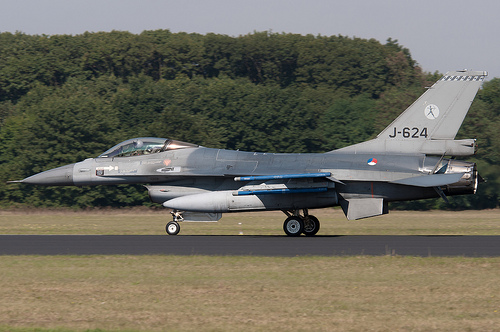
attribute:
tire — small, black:
[283, 213, 306, 238]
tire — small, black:
[304, 213, 322, 236]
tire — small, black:
[165, 217, 181, 238]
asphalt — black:
[0, 233, 497, 254]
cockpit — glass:
[108, 133, 166, 163]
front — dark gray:
[6, 159, 74, 198]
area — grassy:
[0, 253, 496, 329]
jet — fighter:
[5, 69, 485, 242]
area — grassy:
[0, 208, 481, 233]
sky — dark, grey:
[1, 0, 484, 72]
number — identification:
[386, 123, 432, 141]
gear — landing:
[164, 204, 324, 238]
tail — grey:
[373, 67, 484, 141]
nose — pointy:
[4, 159, 78, 189]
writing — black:
[384, 122, 431, 142]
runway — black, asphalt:
[0, 234, 485, 256]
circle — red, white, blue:
[363, 152, 379, 168]